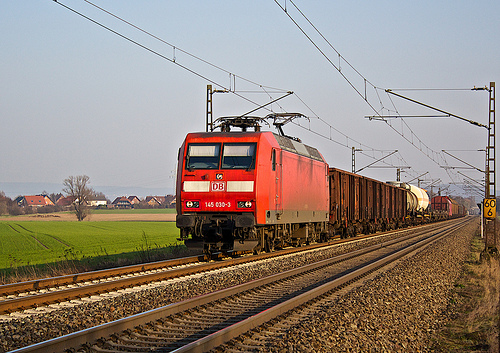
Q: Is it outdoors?
A: Yes, it is outdoors.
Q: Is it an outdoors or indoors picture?
A: It is outdoors.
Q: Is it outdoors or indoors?
A: It is outdoors.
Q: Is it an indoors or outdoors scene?
A: It is outdoors.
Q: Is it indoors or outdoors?
A: It is outdoors.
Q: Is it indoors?
A: No, it is outdoors.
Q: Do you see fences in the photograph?
A: No, there are no fences.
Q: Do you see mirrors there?
A: No, there are no mirrors.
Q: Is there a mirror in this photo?
A: No, there are no mirrors.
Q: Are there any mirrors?
A: No, there are no mirrors.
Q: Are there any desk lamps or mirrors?
A: No, there are no mirrors or desk lamps.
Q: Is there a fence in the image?
A: No, there are no fences.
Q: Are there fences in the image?
A: No, there are no fences.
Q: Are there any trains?
A: Yes, there is a train.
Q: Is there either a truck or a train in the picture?
A: Yes, there is a train.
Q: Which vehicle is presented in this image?
A: The vehicle is a train.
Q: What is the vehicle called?
A: The vehicle is a train.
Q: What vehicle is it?
A: The vehicle is a train.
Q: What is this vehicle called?
A: This is a train.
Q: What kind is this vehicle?
A: This is a train.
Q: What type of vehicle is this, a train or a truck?
A: This is a train.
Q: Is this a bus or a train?
A: This is a train.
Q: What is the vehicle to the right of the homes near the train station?
A: The vehicle is a train.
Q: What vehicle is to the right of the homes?
A: The vehicle is a train.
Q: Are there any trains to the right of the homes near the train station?
A: Yes, there is a train to the right of the homes.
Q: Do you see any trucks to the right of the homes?
A: No, there is a train to the right of the homes.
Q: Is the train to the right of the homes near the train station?
A: Yes, the train is to the right of the homes.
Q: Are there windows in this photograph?
A: Yes, there are windows.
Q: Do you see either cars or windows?
A: Yes, there are windows.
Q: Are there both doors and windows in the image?
A: No, there are windows but no doors.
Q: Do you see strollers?
A: No, there are no strollers.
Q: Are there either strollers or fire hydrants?
A: No, there are no strollers or fire hydrants.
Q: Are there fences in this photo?
A: No, there are no fences.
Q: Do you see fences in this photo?
A: No, there are no fences.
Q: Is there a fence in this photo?
A: No, there are no fences.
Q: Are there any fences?
A: No, there are no fences.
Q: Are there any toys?
A: No, there are no toys.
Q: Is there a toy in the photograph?
A: No, there are no toys.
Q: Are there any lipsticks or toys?
A: No, there are no toys or lipsticks.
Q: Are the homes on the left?
A: Yes, the homes are on the left of the image.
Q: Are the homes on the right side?
A: No, the homes are on the left of the image.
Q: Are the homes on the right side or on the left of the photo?
A: The homes are on the left of the image.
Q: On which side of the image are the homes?
A: The homes are on the left of the image.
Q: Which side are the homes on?
A: The homes are on the left of the image.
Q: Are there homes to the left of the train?
A: Yes, there are homes to the left of the train.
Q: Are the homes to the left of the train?
A: Yes, the homes are to the left of the train.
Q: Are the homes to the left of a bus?
A: No, the homes are to the left of the train.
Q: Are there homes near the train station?
A: Yes, there are homes near the train station.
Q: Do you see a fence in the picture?
A: No, there are no fences.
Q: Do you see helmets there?
A: No, there are no helmets.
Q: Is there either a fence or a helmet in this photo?
A: No, there are no helmets or fences.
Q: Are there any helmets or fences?
A: No, there are no helmets or fences.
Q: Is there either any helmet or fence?
A: No, there are no helmets or fences.